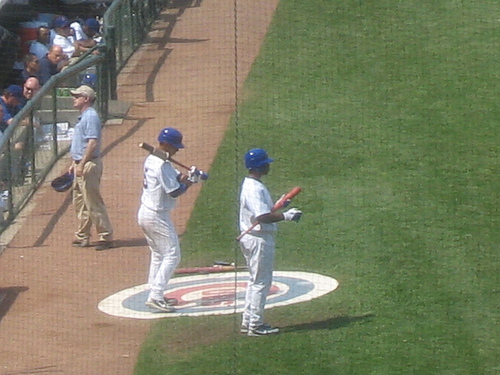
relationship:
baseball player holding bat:
[133, 134, 205, 175] [128, 126, 209, 184]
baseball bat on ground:
[171, 267, 246, 273] [168, 224, 314, 331]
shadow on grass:
[276, 295, 396, 353] [312, 323, 383, 369]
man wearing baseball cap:
[57, 82, 110, 257] [68, 71, 105, 99]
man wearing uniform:
[235, 144, 302, 339] [240, 179, 276, 325]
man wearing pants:
[57, 82, 110, 257] [67, 159, 115, 242]